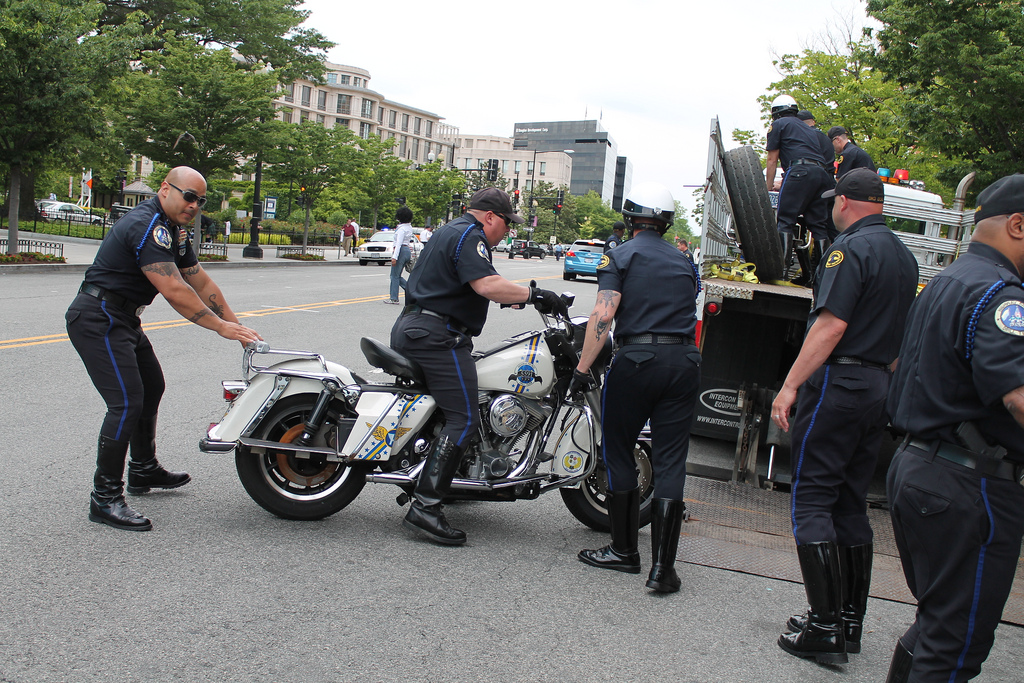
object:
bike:
[202, 282, 660, 532]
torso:
[351, 309, 479, 451]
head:
[622, 186, 676, 237]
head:
[822, 167, 885, 231]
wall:
[124, 64, 571, 227]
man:
[63, 165, 261, 532]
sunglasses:
[169, 183, 208, 209]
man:
[391, 187, 563, 544]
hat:
[466, 187, 524, 223]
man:
[766, 95, 831, 286]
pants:
[777, 163, 838, 240]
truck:
[695, 115, 975, 511]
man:
[570, 175, 702, 591]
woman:
[383, 208, 413, 304]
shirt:
[391, 223, 415, 260]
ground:
[0, 254, 1024, 683]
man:
[884, 174, 1024, 683]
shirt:
[892, 239, 1024, 465]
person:
[342, 218, 359, 258]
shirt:
[340, 224, 354, 237]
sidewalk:
[0, 230, 359, 265]